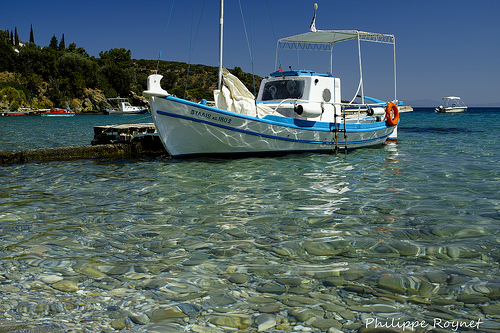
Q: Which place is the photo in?
A: It is at the lake.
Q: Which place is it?
A: It is a lake.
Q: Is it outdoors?
A: Yes, it is outdoors.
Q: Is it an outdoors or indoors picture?
A: It is outdoors.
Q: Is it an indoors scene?
A: No, it is outdoors.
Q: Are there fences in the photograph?
A: No, there are no fences.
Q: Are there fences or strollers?
A: No, there are no fences or strollers.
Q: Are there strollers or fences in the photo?
A: No, there are no fences or strollers.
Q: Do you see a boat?
A: Yes, there is a boat.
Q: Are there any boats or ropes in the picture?
A: Yes, there is a boat.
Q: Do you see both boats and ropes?
A: No, there is a boat but no ropes.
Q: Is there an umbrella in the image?
A: No, there are no umbrellas.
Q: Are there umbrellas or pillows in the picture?
A: No, there are no umbrellas or pillows.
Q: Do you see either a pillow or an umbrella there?
A: No, there are no umbrellas or pillows.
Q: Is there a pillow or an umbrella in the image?
A: No, there are no umbrellas or pillows.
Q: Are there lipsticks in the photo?
A: No, there are no lipsticks.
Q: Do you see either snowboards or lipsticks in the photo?
A: No, there are no lipsticks or snowboards.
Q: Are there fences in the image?
A: No, there are no fences.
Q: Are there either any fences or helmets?
A: No, there are no fences or helmets.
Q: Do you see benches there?
A: No, there are no benches.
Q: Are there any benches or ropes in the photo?
A: No, there are no benches or ropes.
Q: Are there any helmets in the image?
A: No, there are no helmets.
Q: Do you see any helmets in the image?
A: No, there are no helmets.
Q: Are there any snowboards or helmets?
A: No, there are no helmets or snowboards.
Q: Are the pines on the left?
A: Yes, the pines are on the left of the image.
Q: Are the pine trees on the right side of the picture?
A: No, the pine trees are on the left of the image.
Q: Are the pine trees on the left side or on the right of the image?
A: The pine trees are on the left of the image.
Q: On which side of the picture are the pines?
A: The pines are on the left of the image.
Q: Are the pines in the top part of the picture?
A: Yes, the pines are in the top of the image.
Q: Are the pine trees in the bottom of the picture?
A: No, the pine trees are in the top of the image.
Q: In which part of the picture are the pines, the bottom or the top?
A: The pines are in the top of the image.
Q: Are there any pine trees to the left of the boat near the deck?
A: Yes, there are pine trees to the left of the boat.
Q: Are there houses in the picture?
A: No, there are no houses.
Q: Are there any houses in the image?
A: No, there are no houses.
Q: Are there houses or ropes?
A: No, there are no houses or ropes.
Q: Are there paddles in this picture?
A: No, there are no paddles.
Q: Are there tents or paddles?
A: No, there are no paddles or tents.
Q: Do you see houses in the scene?
A: No, there are no houses.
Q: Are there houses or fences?
A: No, there are no houses or fences.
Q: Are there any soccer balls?
A: No, there are no soccer balls.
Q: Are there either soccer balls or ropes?
A: No, there are no soccer balls or ropes.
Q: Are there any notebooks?
A: No, there are no notebooks.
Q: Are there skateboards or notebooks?
A: No, there are no notebooks or skateboards.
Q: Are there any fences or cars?
A: No, there are no cars or fences.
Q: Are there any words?
A: Yes, there are words.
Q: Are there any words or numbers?
A: Yes, there are words.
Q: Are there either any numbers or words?
A: Yes, there are words.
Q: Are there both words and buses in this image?
A: No, there are words but no buses.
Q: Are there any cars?
A: No, there are no cars.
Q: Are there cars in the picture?
A: No, there are no cars.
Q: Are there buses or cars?
A: No, there are no cars or buses.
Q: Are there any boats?
A: Yes, there is a boat.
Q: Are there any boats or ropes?
A: Yes, there is a boat.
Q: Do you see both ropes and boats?
A: No, there is a boat but no ropes.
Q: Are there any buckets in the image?
A: No, there are no buckets.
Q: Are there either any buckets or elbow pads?
A: No, there are no buckets or elbow pads.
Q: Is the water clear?
A: Yes, the water is clear.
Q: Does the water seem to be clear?
A: Yes, the water is clear.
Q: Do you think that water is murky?
A: No, the water is clear.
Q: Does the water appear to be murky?
A: No, the water is clear.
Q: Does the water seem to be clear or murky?
A: The water is clear.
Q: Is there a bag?
A: No, there are no bags.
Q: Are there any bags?
A: No, there are no bags.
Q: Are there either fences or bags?
A: No, there are no bags or fences.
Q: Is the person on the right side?
A: Yes, the person is on the right of the image.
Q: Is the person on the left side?
A: No, the person is on the right of the image.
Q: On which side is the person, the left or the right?
A: The person is on the right of the image.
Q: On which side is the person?
A: The person is on the right of the image.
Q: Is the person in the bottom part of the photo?
A: Yes, the person is in the bottom of the image.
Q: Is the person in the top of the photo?
A: No, the person is in the bottom of the image.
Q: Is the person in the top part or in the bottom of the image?
A: The person is in the bottom of the image.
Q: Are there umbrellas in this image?
A: No, there are no umbrellas.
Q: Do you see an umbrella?
A: No, there are no umbrellas.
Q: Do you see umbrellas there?
A: No, there are no umbrellas.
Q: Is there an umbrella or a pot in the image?
A: No, there are no umbrellas or pots.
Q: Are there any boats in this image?
A: Yes, there is a boat.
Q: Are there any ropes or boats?
A: Yes, there is a boat.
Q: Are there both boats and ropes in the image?
A: No, there is a boat but no ropes.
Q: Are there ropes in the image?
A: No, there are no ropes.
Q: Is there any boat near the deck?
A: Yes, there is a boat near the deck.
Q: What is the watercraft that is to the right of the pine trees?
A: The watercraft is a boat.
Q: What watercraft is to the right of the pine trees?
A: The watercraft is a boat.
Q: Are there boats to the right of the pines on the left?
A: Yes, there is a boat to the right of the pine trees.